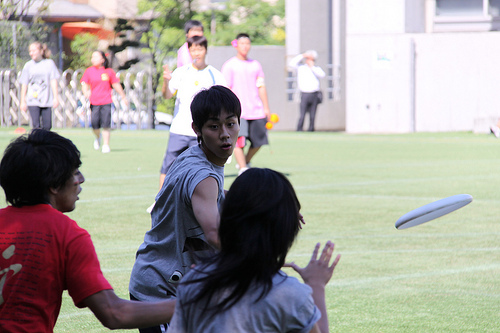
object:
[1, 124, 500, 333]
ground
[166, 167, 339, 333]
woman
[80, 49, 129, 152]
woman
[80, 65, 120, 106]
red shirt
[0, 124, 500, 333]
field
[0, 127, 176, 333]
man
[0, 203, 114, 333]
red shirt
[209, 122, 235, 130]
man's eyes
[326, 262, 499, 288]
boundary line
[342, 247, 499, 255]
boundary line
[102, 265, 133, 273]
boundary line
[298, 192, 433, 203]
boundary line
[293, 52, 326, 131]
man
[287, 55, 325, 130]
uniform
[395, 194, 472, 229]
floater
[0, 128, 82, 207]
hair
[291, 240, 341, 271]
finger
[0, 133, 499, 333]
green grass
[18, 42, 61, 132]
person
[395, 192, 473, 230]
frisbee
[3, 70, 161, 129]
fence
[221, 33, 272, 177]
man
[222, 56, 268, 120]
shirt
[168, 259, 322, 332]
shirt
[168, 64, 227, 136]
white shirt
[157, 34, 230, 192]
man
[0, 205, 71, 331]
back